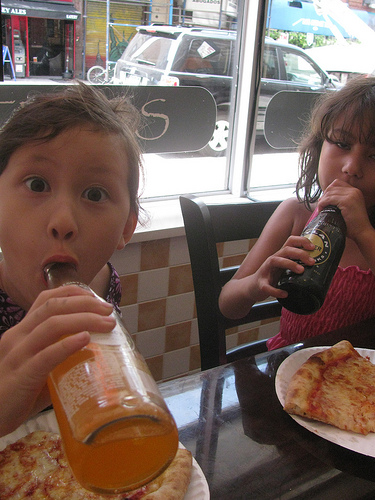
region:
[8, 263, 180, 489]
glass bottle of orange soda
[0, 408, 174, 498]
pizza on white paper plate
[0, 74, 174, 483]
small girl drinking soda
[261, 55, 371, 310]
girl drinking bottle of soda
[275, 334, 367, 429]
pizza on white paper plate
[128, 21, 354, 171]
black suv on road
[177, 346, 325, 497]
glass table near girls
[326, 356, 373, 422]
melted cheese on pizza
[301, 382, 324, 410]
red tomato sauce on pizza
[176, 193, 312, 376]
black chair behind girl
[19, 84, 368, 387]
kids drinking pop at a restuarant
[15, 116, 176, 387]
this child has an orange pop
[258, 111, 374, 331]
this child has a dark colored pop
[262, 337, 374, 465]
a slice of cheese pizza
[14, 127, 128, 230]
this child has wide eyes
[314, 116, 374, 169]
her eyes look sleepy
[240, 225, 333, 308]
the girl's fingers are spread out on the bottle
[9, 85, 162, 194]
this girl's hair is somewhat messy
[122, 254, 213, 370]
a yellow and white checkered wall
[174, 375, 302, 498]
a wooden table with a plastic coating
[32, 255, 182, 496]
clear glass bottle with orange soda inside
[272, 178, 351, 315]
dark brown glass soda bottle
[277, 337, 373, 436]
white yellow and red slice of pizza on white plate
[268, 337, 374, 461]
circular white paper plate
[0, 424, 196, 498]
yellow white and red slice of pizza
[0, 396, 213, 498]
circular white paper plate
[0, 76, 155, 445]
child sitting at table drinking orange soda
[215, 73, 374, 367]
child sitting at table drinking soda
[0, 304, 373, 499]
dark brown wooden table with reflective surface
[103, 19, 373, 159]
car parked next to pizza shop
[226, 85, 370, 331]
the girl is drinking beer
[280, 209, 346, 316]
the beer is brown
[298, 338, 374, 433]
the pizza is yellow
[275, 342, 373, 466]
the plate is white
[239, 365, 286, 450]
shadow is on the table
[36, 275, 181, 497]
the juice is orange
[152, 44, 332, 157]
the car is black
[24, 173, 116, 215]
eyes are wide open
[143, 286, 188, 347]
the wall is brown and white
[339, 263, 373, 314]
the dress is pink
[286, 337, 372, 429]
a huge slice of pizza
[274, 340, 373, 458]
pizza on a white plate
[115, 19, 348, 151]
a black suv car outside the restaurant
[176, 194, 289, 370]
black wooden chair carrying the girl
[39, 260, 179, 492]
orange drink in bottle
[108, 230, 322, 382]
white and brown tiled wall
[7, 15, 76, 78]
red pillars in a store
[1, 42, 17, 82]
blue sign board in front of a store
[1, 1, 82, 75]
black roof on red pillars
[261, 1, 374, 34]
blue canopy with white writings